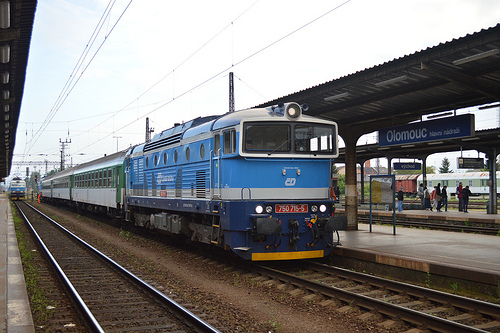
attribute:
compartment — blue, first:
[123, 97, 337, 266]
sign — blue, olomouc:
[372, 112, 477, 149]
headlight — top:
[285, 101, 302, 118]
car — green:
[71, 143, 132, 220]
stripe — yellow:
[245, 240, 335, 262]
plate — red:
[269, 192, 317, 218]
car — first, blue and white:
[175, 112, 326, 242]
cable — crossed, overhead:
[26, 0, 349, 167]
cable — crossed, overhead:
[49, 2, 259, 157]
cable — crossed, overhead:
[6, 2, 132, 180]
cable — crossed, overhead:
[4, 0, 115, 181]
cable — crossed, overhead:
[18, 2, 109, 164]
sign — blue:
[366, 103, 493, 164]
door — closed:
[211, 137, 219, 197]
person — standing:
[391, 187, 407, 213]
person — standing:
[455, 181, 465, 211]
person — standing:
[461, 179, 472, 210]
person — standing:
[439, 183, 452, 214]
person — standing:
[419, 186, 435, 214]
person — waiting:
[435, 181, 453, 214]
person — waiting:
[392, 183, 406, 213]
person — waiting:
[429, 181, 445, 212]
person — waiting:
[456, 179, 466, 208]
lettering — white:
[380, 123, 460, 138]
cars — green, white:
[41, 144, 131, 213]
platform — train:
[285, 188, 498, 298]